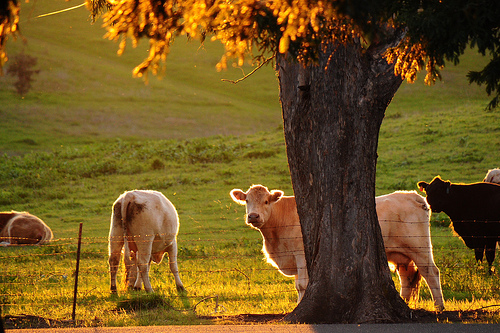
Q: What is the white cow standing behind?
A: A tree.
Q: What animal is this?
A: Cow.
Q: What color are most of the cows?
A: White.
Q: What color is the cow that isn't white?
A: Brown.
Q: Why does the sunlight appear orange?
A: It's Sunset.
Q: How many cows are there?
A: Five.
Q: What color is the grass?
A: Green.